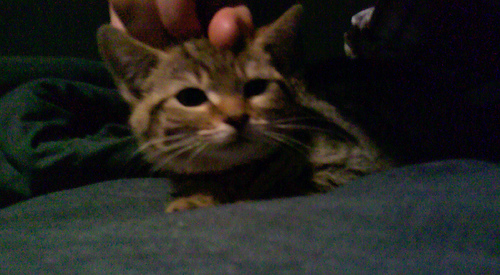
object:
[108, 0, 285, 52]
hand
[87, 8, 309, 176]
head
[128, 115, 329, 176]
whiskers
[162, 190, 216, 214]
paw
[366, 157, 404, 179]
ground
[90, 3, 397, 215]
cat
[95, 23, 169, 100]
ear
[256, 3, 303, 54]
ear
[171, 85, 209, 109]
black eyes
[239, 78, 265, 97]
eye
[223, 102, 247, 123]
nose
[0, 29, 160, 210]
blanket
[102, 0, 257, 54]
person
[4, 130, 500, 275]
bed